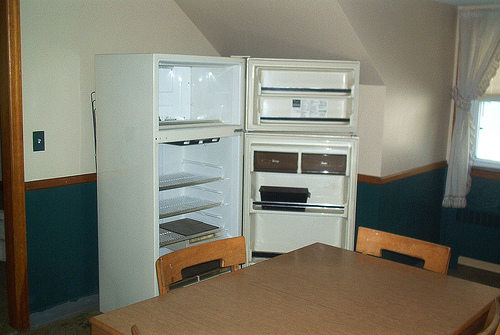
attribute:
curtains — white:
[443, 5, 492, 227]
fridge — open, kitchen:
[90, 37, 387, 314]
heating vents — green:
[432, 201, 499, 263]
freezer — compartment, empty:
[161, 59, 238, 124]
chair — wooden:
[341, 215, 461, 284]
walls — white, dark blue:
[25, 2, 498, 312]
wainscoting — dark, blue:
[38, 185, 85, 293]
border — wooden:
[362, 157, 451, 185]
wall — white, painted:
[23, 3, 92, 127]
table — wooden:
[86, 237, 498, 333]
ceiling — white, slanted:
[177, 8, 388, 88]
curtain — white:
[428, 38, 478, 275]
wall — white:
[30, 20, 75, 99]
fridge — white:
[88, 48, 357, 255]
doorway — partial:
[6, 5, 59, 325]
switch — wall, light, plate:
[30, 128, 43, 152]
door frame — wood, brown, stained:
[3, 2, 23, 334]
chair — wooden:
[334, 221, 468, 300]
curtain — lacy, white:
[442, 7, 499, 210]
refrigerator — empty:
[92, 46, 362, 313]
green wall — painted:
[23, 180, 99, 329]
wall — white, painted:
[333, 16, 470, 160]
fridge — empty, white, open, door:
[93, 48, 365, 302]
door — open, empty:
[243, 55, 363, 258]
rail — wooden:
[24, 161, 498, 191]